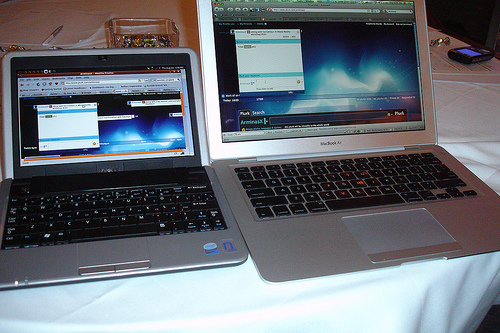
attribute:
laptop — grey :
[189, 0, 497, 288]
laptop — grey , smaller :
[1, 46, 240, 284]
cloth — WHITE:
[1, 54, 493, 332]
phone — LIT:
[450, 50, 490, 76]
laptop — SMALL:
[2, 83, 282, 273]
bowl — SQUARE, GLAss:
[113, 50, 117, 58]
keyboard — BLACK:
[7, 177, 226, 260]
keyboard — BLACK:
[3, 183, 222, 273]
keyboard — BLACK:
[41, 78, 213, 281]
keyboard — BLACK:
[5, 185, 225, 261]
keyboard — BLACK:
[7, 170, 234, 258]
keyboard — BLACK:
[1, 110, 241, 292]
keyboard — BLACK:
[5, 181, 225, 255]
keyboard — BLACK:
[5, 176, 225, 244]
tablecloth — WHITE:
[39, 110, 499, 333]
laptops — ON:
[5, 55, 498, 299]